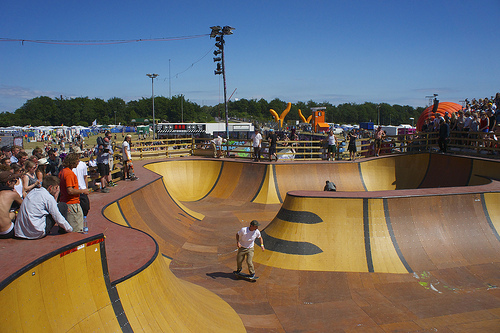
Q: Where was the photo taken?
A: Skateboard rink.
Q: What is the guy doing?
A: Skateboarding.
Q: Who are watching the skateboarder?
A: Fans.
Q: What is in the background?
A: Trees.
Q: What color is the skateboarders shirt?
A: White.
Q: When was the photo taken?
A: During the day.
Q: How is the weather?
A: Clear.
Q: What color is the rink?
A: Brown.